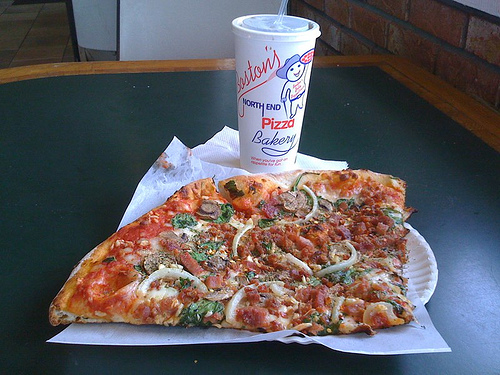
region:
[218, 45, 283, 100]
The word Boston's on a cup.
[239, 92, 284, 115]
The words North End in blue letters.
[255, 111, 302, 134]
The word Pizza in red letters.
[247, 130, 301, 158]
The word Bakery in blue letters.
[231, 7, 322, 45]
Plastic lid on a cup.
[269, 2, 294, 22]
Drinking straw in a cup.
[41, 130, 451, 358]
Two large slices of pizza.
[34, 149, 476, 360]
Pizza slices on a paper plate.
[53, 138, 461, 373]
White paper under the pizza.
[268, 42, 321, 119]
A figure on a cup.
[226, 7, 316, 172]
Large cup with a beverage in it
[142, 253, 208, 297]
Onions and sausage on pizza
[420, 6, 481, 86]
Wall made out of bricks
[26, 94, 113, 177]
Smooth green table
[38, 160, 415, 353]
Two slices of an vegetable pizza with sausage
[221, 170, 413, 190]
Crust of the pizza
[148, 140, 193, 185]
Small part of napkin with grease on it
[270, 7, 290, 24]
Mid-section of the straw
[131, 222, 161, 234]
Tomato sauce on pizza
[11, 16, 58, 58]
Floor made out of tiles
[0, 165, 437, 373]
Two large slices of pizza.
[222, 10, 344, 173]
A cup of soda to drink.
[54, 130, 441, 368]
Paper towels under the pizza and the cup.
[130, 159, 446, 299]
A paper plate under the pizza.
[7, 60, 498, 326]
A large table under the food and drink.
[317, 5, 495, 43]
An old brick wall.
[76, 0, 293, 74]
A large white object behind the table.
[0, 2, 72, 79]
A brown tile floor.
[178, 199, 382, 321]
Many toppings on the pizza.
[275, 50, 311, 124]
A mascot for the company.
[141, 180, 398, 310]
this is a pizza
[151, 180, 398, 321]
thew pizza is spicy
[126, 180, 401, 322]
the pizza is big in size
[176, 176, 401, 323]
the pizza is red in color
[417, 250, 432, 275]
this is a plate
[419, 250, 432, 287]
the plate is white in color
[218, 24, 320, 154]
this is a container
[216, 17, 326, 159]
the container is white in color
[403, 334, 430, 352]
this is a saviet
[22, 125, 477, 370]
Two slices of pizza.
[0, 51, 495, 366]
The food is on a table.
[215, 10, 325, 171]
A large drink.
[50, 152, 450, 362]
The pizza is on top of a piece of paper.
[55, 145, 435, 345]
The plate the pizza is on is made from paper.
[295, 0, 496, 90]
A brick wall.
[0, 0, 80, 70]
A tile floor.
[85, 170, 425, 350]
The pizza has onions on it.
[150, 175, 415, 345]
Green shreds of basil can be seen on the pizza.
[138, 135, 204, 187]
Grease and food residue from the pizza.